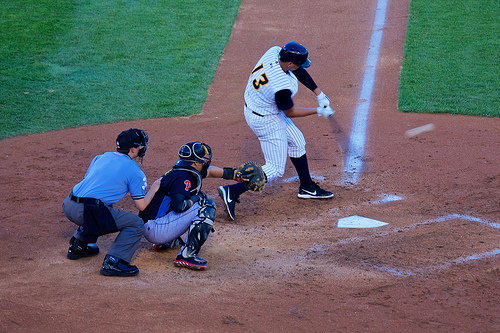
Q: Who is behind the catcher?
A: Umpire.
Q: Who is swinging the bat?
A: Player 13.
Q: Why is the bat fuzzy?
A: Bat is in motion.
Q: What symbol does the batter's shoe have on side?
A: Nike Swoosh.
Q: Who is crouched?
A: Catcher.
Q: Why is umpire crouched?
A: Watching play.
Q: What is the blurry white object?
A: Baseball in motion.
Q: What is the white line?
A: 3rd base line.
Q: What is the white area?
A: Batters box.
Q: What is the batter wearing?
A: A safety helmet.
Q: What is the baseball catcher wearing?
A: A mitt.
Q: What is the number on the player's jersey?
A: Thirteen.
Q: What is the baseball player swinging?
A: A bat.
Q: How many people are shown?
A: Three.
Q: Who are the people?
A: Baseball players.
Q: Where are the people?
A: Baseball field.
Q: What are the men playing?
A: Baseball.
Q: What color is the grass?
A: Green.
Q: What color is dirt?
A: Brown.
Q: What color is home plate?
A: White.